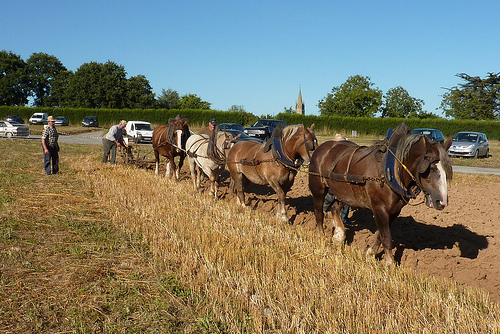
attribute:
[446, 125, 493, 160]
silver car — parked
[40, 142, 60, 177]
jeans — blue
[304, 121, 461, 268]
horse — wide, brown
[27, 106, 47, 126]
car — parked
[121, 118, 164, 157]
car — parked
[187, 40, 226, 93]
clouds — white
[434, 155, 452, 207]
marking — white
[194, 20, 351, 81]
cloud — white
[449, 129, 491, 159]
car — parked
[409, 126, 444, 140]
car — parked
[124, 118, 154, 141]
car — parked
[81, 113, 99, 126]
car — parked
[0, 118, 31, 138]
car — parked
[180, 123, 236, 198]
horse — white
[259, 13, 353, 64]
sky — blue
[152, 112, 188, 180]
brown horse — wide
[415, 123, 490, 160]
cars — parked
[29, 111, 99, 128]
cars — parked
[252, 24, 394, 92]
clouds — white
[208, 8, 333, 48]
sky — blue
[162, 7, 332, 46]
sky — blue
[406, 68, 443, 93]
clouds — white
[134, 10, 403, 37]
sky — blue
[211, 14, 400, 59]
sky — blue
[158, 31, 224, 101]
sky — blue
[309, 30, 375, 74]
clouds — white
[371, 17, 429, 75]
clouds — white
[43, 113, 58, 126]
cap — tan